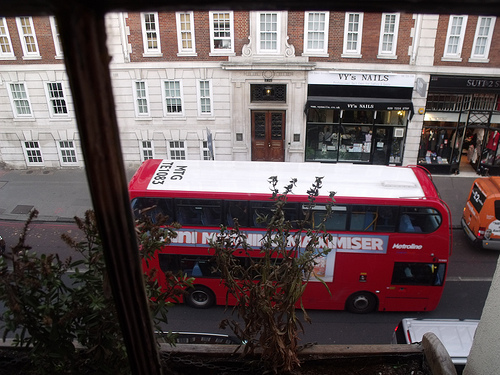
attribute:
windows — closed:
[139, 198, 434, 231]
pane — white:
[207, 16, 219, 52]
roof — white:
[309, 83, 310, 84]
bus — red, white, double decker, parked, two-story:
[139, 159, 430, 316]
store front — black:
[304, 83, 403, 166]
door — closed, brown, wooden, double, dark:
[250, 106, 287, 161]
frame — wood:
[249, 114, 254, 162]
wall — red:
[157, 13, 176, 62]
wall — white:
[182, 71, 199, 120]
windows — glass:
[255, 111, 263, 138]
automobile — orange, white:
[466, 177, 496, 247]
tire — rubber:
[188, 281, 214, 311]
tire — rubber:
[349, 286, 377, 317]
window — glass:
[205, 11, 234, 57]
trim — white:
[228, 11, 237, 53]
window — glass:
[255, 14, 284, 57]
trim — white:
[255, 13, 258, 48]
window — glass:
[302, 15, 333, 57]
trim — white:
[302, 11, 311, 54]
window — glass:
[347, 11, 357, 47]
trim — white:
[339, 14, 353, 52]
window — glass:
[446, 18, 461, 53]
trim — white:
[458, 19, 463, 61]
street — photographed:
[7, 167, 489, 350]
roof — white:
[155, 156, 415, 210]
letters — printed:
[171, 166, 181, 178]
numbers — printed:
[152, 166, 168, 188]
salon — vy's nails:
[308, 69, 412, 182]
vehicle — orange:
[459, 176, 498, 247]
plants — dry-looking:
[14, 215, 89, 374]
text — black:
[155, 156, 188, 185]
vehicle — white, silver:
[400, 314, 499, 357]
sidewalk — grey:
[0, 167, 490, 218]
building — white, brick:
[0, 9, 488, 166]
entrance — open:
[466, 130, 482, 177]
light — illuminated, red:
[476, 229, 480, 238]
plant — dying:
[210, 220, 311, 372]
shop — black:
[306, 88, 399, 166]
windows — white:
[2, 1, 495, 49]